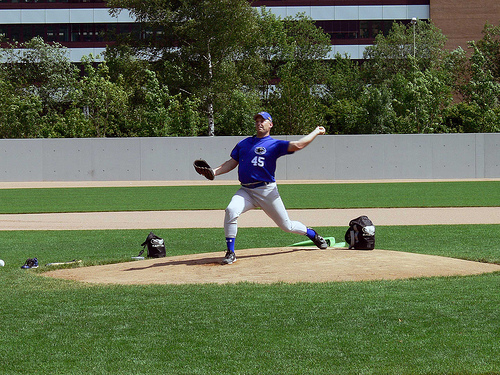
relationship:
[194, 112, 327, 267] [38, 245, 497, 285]
player on mound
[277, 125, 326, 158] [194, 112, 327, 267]
arm of player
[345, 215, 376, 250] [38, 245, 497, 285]
bag on mound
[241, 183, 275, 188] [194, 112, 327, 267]
belt around player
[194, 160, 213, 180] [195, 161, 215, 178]
mitt on hand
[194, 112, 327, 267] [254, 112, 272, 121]
player wearing hat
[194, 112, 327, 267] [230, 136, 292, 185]
player wearing shirt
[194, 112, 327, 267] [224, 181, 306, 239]
player wearing pants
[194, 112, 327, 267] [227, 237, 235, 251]
player wearing sock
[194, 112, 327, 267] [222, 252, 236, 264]
player wearing shoe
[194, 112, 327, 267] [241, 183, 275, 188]
player wearing belt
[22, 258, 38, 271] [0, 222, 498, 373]
shoe sitting in grass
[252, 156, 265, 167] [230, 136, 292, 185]
number on jersey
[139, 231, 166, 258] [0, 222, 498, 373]
bag on grass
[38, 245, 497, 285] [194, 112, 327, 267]
mound for player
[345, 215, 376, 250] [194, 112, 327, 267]
bag for player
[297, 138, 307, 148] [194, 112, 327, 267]
elbow of player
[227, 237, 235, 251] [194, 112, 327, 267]
sock on player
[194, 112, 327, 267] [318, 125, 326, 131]
player throwing ball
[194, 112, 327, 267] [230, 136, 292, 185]
player wearing jersey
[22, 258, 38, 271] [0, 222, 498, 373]
shoe in grass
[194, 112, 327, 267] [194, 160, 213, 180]
player wearing mitt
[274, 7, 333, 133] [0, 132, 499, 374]
tree behind field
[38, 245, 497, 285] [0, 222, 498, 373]
mound surround by grass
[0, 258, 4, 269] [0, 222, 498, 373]
ball on grass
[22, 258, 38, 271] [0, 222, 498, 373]
shoe on grass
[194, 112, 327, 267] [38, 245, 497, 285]
player standing on mound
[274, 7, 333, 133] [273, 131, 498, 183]
tree behind wall